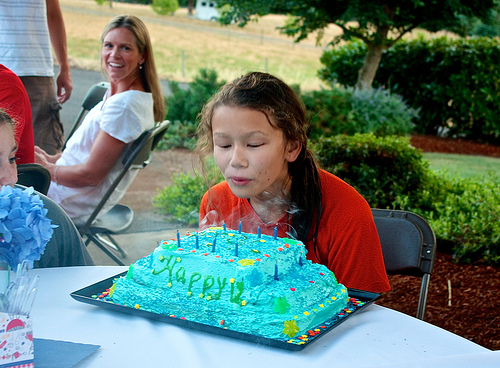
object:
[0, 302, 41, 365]
present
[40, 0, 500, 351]
garden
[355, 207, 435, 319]
chair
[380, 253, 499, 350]
mulch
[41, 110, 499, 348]
ground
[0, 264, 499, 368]
table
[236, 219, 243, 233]
candles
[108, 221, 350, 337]
birthday cake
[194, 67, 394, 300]
girl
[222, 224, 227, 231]
candles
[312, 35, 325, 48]
leaves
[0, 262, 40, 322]
utensils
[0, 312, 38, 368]
box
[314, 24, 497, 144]
shrubbery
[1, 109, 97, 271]
girl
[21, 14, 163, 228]
girl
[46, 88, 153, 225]
shirt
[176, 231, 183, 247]
candle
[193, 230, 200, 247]
candle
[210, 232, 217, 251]
candle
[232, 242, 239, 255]
candle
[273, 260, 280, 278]
candle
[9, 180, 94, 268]
green shirt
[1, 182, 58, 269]
blue flowers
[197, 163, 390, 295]
shirt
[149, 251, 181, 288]
green letter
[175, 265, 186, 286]
green letter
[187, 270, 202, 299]
green letter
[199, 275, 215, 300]
green letter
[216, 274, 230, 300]
green letter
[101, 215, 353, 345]
frosting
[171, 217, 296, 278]
candles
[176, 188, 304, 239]
smoke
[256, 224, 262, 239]
candles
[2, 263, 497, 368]
surface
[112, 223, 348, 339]
icing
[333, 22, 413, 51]
branches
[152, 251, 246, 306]
writing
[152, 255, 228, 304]
word happy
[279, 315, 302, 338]
yellow flower